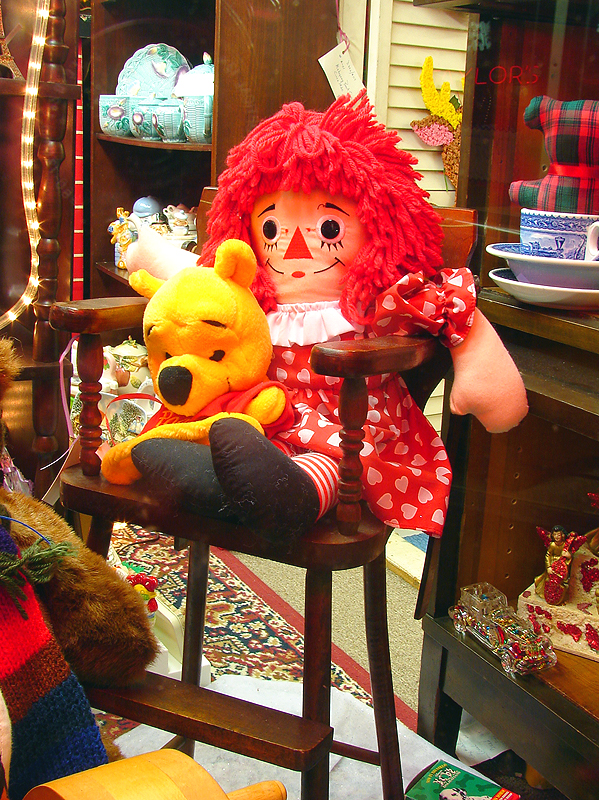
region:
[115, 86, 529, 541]
Raggedy ann doll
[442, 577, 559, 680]
Car filled with candy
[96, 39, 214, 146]
Light green China set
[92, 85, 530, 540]
Pooh bear with raggedy ann doll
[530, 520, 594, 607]
Angel with red wings playing instrument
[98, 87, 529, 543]
Raggedy ann doll sitting with pooh bear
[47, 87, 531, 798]
Raggedy ann doll sitting in high chair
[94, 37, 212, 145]
ceramic tea set on shelf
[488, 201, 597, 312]
blue and white dishes stacked on each other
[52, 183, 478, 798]
wood high chair for play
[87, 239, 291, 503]
stuffed bear from childs story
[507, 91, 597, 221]
stuffed bear made from plaid fabric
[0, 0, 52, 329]
clear, bendable rope lighting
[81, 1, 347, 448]
wooden book shelf full of odds and ends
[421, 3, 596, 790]
wooden display case holding many objects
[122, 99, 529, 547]
soft doll with red yarn hair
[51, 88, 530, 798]
dolls on wood chair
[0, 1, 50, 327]
string of lights in cord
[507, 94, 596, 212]
toy made of plaid material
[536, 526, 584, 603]
angle figure with red instrument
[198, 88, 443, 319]
red yarn on doll head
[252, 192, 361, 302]
doll face with triangle nose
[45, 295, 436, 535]
arms of wood chair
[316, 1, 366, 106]
hanging tag on ribbon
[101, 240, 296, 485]
the winnie the pooh stuffed animal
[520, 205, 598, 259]
the bowl on the top of the bowl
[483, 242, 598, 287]
the bowl resting in the middle of the pile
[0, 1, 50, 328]
the lights strung on the shelf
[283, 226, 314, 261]
the red triangle on the doll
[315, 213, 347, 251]
the round eye on the doll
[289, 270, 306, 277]
the oval red mouth on the face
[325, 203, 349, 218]
the black eyebrow on the doll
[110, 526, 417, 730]
the rug on the floor is colorful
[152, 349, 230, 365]
The eyes of the Pooh bear stuffed toy.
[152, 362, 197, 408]
The nose of the Pooh bear toy.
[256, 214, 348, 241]
The eyes of the doll sitting on the chair.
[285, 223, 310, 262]
The nose of the doll sitting on the chair.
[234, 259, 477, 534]
The dress the doll sitting on the chair is wearing.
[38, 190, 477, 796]
The wooden chair the toys are sitting on.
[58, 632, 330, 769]
The step of the chair the toys are sitting on.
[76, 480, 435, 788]
The rug under the chair.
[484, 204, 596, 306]
The blue and white bowl, plate and cup on the wooden cabinet.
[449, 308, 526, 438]
The arm of the doll sitting on the chair.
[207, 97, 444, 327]
hair on a doll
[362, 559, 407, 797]
leg of a chair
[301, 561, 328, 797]
leg of a chair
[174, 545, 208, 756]
leg of a chair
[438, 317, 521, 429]
arm of a doll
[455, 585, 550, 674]
a weird toy car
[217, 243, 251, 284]
ear of a bear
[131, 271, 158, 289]
ear of a bear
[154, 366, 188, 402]
nose of a bear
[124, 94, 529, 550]
red-haired doll sitting on the chair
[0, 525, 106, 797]
red blue and brown knitted scarf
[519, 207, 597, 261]
large blue and white cup on the right from the doll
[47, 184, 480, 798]
wooden chair the doll is sitting on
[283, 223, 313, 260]
the doll's triangular nose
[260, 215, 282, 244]
the doll's right eye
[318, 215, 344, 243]
the doll's left eye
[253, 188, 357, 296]
the doll's face